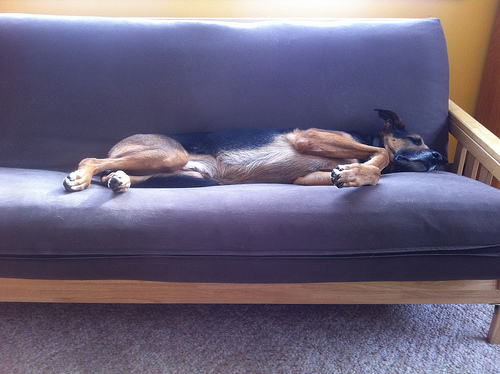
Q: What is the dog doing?
A: Sleeping.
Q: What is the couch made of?
A: Wood.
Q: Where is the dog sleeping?
A: On a couch.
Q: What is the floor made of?
A: Carpet.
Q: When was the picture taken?
A: On a sunny day.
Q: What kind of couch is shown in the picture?
A: Foam made couch.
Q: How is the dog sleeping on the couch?
A: On its side.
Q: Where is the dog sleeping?
A: On a futon couch.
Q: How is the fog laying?
A: On its side.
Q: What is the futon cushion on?
A: A wooden frame.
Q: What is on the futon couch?
A: A dog.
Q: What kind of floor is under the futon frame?
A: A carpeted floor.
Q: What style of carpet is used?
A: Berber carpet.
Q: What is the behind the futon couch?
A: A wall.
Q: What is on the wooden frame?
A: A futon cushion.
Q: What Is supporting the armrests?
A: Wood slats.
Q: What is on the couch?
A: A dog.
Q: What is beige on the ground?
A: Carpet.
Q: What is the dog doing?
A: Sleeping.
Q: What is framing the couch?
A: Wood.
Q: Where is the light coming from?
A: Sunshine.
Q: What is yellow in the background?
A: Wall.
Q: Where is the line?
A: Along couch.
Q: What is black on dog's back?
A: Fur.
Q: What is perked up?
A: Dog's ear.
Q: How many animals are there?
A: One.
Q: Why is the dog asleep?
A: He is tired.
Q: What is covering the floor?
A: Carpet.